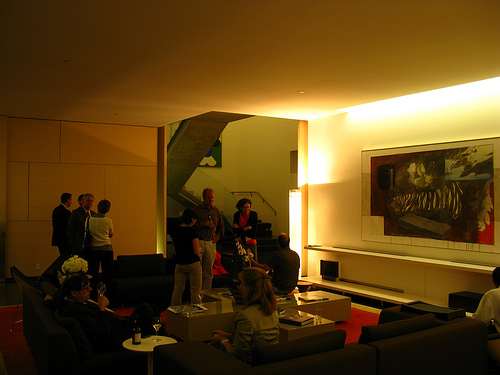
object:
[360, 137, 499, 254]
picture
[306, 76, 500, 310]
wall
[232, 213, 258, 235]
arm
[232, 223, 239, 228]
lady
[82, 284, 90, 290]
eyeglasses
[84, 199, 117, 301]
bad people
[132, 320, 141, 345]
bottle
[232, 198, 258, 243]
people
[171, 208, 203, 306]
people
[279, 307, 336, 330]
table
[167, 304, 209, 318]
book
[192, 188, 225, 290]
man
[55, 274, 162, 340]
man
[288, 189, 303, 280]
light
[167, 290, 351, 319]
table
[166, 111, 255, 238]
bad staircase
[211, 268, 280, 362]
person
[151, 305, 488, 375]
chair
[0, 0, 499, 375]
room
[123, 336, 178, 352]
table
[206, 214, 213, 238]
bottle